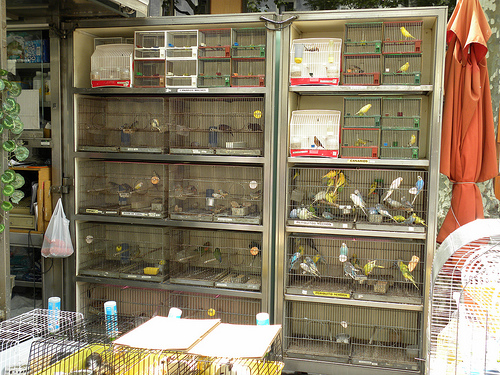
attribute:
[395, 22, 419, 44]
bird — yellow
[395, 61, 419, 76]
bird — yellow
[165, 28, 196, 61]
cage — white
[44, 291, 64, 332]
water bottle — blue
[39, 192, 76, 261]
bag — white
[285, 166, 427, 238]
crate — full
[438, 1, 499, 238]
umbrella — orange, tied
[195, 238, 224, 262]
birds — green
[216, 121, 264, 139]
birds — brown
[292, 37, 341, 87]
cage — white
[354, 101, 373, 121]
parakeet — yellow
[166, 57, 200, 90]
cage — white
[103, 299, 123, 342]
water bottle — blue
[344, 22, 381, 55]
green cage — empty